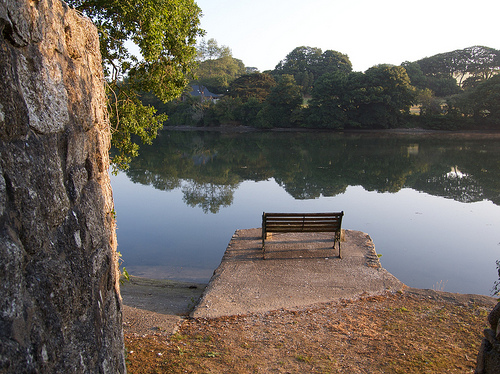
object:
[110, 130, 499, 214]
reflection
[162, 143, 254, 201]
water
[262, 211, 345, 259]
bench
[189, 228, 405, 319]
concrete surface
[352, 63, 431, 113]
trees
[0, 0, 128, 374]
tree bark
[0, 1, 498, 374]
picture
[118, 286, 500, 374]
ground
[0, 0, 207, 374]
tree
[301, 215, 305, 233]
vertical slat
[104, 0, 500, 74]
sky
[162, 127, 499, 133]
shore